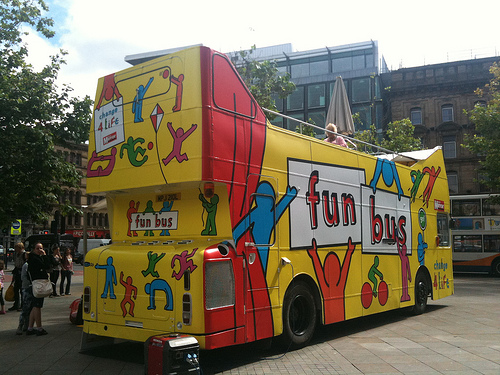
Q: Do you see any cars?
A: No, there are no cars.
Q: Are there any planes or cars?
A: No, there are no cars or planes.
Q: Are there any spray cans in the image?
A: No, there are no spray cans.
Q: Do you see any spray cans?
A: No, there are no spray cans.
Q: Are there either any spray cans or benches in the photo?
A: No, there are no spray cans or benches.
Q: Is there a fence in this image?
A: No, there are no fences.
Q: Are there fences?
A: No, there are no fences.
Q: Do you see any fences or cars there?
A: No, there are no fences or cars.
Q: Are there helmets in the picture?
A: No, there are no helmets.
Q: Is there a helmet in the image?
A: No, there are no helmets.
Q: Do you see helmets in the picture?
A: No, there are no helmets.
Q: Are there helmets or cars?
A: No, there are no helmets or cars.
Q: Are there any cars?
A: No, there are no cars.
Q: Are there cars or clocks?
A: No, there are no cars or clocks.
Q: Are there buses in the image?
A: Yes, there is a bus.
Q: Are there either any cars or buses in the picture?
A: Yes, there is a bus.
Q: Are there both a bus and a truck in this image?
A: No, there is a bus but no trucks.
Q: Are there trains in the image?
A: No, there are no trains.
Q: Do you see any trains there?
A: No, there are no trains.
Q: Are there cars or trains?
A: No, there are no trains or cars.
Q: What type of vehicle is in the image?
A: The vehicle is a bus.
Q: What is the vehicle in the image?
A: The vehicle is a bus.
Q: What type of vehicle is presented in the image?
A: The vehicle is a bus.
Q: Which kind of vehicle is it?
A: The vehicle is a bus.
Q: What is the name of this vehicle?
A: This is a bus.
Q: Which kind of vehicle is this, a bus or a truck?
A: This is a bus.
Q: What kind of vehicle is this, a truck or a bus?
A: This is a bus.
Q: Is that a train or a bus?
A: That is a bus.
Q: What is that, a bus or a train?
A: That is a bus.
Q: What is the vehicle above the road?
A: The vehicle is a bus.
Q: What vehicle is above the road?
A: The vehicle is a bus.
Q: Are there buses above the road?
A: Yes, there is a bus above the road.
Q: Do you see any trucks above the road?
A: No, there is a bus above the road.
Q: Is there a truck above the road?
A: No, there is a bus above the road.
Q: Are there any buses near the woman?
A: Yes, there is a bus near the woman.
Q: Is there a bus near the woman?
A: Yes, there is a bus near the woman.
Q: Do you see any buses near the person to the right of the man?
A: Yes, there is a bus near the woman.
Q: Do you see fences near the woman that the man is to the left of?
A: No, there is a bus near the woman.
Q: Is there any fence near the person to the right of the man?
A: No, there is a bus near the woman.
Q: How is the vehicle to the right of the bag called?
A: The vehicle is a bus.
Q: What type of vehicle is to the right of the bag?
A: The vehicle is a bus.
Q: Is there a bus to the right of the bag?
A: Yes, there is a bus to the right of the bag.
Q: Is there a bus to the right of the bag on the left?
A: Yes, there is a bus to the right of the bag.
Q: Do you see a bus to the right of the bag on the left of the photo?
A: Yes, there is a bus to the right of the bag.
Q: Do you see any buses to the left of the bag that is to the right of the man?
A: No, the bus is to the right of the bag.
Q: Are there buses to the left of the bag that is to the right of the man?
A: No, the bus is to the right of the bag.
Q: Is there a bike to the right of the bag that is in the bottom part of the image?
A: No, there is a bus to the right of the bag.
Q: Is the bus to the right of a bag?
A: Yes, the bus is to the right of a bag.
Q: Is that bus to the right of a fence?
A: No, the bus is to the right of a bag.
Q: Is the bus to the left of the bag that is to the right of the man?
A: No, the bus is to the right of the bag.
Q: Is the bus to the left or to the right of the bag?
A: The bus is to the right of the bag.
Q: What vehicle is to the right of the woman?
A: The vehicle is a bus.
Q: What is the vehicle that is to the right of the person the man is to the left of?
A: The vehicle is a bus.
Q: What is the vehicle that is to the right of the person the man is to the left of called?
A: The vehicle is a bus.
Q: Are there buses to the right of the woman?
A: Yes, there is a bus to the right of the woman.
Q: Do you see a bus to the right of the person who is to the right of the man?
A: Yes, there is a bus to the right of the woman.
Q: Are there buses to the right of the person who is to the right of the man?
A: Yes, there is a bus to the right of the woman.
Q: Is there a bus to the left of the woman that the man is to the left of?
A: No, the bus is to the right of the woman.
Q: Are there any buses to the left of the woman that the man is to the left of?
A: No, the bus is to the right of the woman.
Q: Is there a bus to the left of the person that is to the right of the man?
A: No, the bus is to the right of the woman.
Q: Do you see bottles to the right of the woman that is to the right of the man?
A: No, there is a bus to the right of the woman.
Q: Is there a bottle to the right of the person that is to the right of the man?
A: No, there is a bus to the right of the woman.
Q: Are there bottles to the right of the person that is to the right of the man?
A: No, there is a bus to the right of the woman.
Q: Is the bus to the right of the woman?
A: Yes, the bus is to the right of the woman.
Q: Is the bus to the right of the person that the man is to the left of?
A: Yes, the bus is to the right of the woman.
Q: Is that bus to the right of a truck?
A: No, the bus is to the right of the woman.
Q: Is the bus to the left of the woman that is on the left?
A: No, the bus is to the right of the woman.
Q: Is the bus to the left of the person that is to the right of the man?
A: No, the bus is to the right of the woman.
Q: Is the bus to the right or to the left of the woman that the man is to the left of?
A: The bus is to the right of the woman.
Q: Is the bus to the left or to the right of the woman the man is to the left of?
A: The bus is to the right of the woman.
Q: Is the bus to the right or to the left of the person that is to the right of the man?
A: The bus is to the right of the woman.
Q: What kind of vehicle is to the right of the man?
A: The vehicle is a bus.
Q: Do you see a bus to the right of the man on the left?
A: Yes, there is a bus to the right of the man.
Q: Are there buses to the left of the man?
A: No, the bus is to the right of the man.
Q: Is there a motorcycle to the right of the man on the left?
A: No, there is a bus to the right of the man.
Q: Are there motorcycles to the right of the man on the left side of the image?
A: No, there is a bus to the right of the man.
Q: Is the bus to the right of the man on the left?
A: Yes, the bus is to the right of the man.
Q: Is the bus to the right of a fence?
A: No, the bus is to the right of the man.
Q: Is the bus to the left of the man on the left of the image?
A: No, the bus is to the right of the man.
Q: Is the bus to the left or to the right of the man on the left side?
A: The bus is to the right of the man.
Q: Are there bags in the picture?
A: Yes, there is a bag.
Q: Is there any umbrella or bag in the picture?
A: Yes, there is a bag.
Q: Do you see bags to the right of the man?
A: Yes, there is a bag to the right of the man.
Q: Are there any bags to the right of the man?
A: Yes, there is a bag to the right of the man.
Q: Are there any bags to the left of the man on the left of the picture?
A: No, the bag is to the right of the man.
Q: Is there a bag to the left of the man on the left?
A: No, the bag is to the right of the man.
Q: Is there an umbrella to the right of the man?
A: No, there is a bag to the right of the man.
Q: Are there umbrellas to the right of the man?
A: No, there is a bag to the right of the man.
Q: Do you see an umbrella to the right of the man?
A: No, there is a bag to the right of the man.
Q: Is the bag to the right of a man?
A: Yes, the bag is to the right of a man.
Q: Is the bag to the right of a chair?
A: No, the bag is to the right of a man.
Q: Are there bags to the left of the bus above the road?
A: Yes, there is a bag to the left of the bus.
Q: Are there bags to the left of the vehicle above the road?
A: Yes, there is a bag to the left of the bus.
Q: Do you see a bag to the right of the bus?
A: No, the bag is to the left of the bus.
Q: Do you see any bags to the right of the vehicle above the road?
A: No, the bag is to the left of the bus.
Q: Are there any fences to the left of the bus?
A: No, there is a bag to the left of the bus.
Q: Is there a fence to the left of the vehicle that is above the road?
A: No, there is a bag to the left of the bus.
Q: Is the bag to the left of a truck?
A: No, the bag is to the left of a bus.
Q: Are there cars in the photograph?
A: No, there are no cars.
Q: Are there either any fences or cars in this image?
A: No, there are no cars or fences.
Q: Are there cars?
A: No, there are no cars.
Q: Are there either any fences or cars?
A: No, there are no cars or fences.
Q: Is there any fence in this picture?
A: No, there are no fences.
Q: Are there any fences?
A: No, there are no fences.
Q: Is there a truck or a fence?
A: No, there are no fences or trucks.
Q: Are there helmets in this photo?
A: No, there are no helmets.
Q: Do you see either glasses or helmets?
A: No, there are no helmets or glasses.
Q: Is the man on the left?
A: Yes, the man is on the left of the image.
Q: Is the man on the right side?
A: No, the man is on the left of the image.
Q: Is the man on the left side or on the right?
A: The man is on the left of the image.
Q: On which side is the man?
A: The man is on the left of the image.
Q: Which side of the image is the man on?
A: The man is on the left of the image.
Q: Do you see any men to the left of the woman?
A: Yes, there is a man to the left of the woman.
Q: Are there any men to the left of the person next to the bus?
A: Yes, there is a man to the left of the woman.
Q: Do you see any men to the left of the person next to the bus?
A: Yes, there is a man to the left of the woman.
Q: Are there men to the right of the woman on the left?
A: No, the man is to the left of the woman.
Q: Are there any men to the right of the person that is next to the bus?
A: No, the man is to the left of the woman.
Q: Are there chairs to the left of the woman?
A: No, there is a man to the left of the woman.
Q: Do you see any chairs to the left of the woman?
A: No, there is a man to the left of the woman.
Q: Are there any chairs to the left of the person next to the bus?
A: No, there is a man to the left of the woman.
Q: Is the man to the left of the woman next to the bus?
A: Yes, the man is to the left of the woman.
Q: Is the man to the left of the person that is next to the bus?
A: Yes, the man is to the left of the woman.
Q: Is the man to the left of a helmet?
A: No, the man is to the left of the woman.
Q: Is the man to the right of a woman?
A: No, the man is to the left of a woman.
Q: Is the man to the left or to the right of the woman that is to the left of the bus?
A: The man is to the left of the woman.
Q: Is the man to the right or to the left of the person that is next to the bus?
A: The man is to the left of the woman.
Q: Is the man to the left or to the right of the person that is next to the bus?
A: The man is to the left of the woman.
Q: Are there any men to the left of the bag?
A: Yes, there is a man to the left of the bag.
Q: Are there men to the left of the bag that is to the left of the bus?
A: Yes, there is a man to the left of the bag.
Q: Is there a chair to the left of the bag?
A: No, there is a man to the left of the bag.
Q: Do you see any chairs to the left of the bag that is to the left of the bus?
A: No, there is a man to the left of the bag.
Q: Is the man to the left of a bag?
A: Yes, the man is to the left of a bag.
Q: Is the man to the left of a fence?
A: No, the man is to the left of a bag.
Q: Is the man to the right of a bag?
A: No, the man is to the left of a bag.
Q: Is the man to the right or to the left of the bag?
A: The man is to the left of the bag.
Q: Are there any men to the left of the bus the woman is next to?
A: Yes, there is a man to the left of the bus.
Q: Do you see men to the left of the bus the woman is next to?
A: Yes, there is a man to the left of the bus.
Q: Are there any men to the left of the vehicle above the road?
A: Yes, there is a man to the left of the bus.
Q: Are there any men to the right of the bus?
A: No, the man is to the left of the bus.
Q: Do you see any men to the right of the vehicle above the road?
A: No, the man is to the left of the bus.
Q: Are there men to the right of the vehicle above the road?
A: No, the man is to the left of the bus.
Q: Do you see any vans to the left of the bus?
A: No, there is a man to the left of the bus.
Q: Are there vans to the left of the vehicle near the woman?
A: No, there is a man to the left of the bus.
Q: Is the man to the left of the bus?
A: Yes, the man is to the left of the bus.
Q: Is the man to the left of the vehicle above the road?
A: Yes, the man is to the left of the bus.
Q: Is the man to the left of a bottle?
A: No, the man is to the left of the bus.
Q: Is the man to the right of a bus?
A: No, the man is to the left of a bus.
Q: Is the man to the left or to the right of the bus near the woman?
A: The man is to the left of the bus.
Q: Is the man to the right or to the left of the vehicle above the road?
A: The man is to the left of the bus.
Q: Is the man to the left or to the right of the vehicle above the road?
A: The man is to the left of the bus.